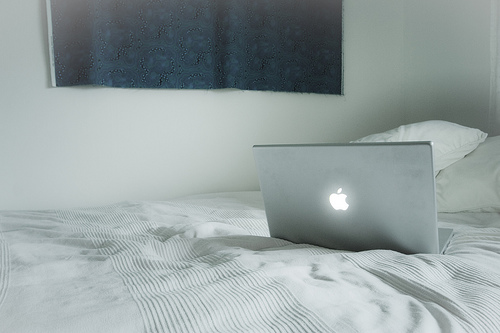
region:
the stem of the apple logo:
[333, 186, 343, 196]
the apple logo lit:
[329, 186, 349, 213]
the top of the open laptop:
[252, 137, 443, 255]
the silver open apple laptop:
[254, 135, 454, 259]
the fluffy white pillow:
[350, 118, 487, 179]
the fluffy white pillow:
[429, 132, 499, 207]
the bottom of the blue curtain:
[45, 2, 348, 96]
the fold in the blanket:
[360, 263, 458, 319]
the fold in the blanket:
[402, 293, 420, 331]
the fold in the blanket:
[426, 299, 452, 331]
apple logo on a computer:
[320, 183, 355, 217]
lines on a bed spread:
[155, 262, 227, 307]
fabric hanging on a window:
[120, 25, 263, 89]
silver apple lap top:
[238, 112, 463, 267]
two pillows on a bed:
[418, 91, 485, 210]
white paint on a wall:
[7, 103, 92, 160]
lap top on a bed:
[223, 116, 468, 291]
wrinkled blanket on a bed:
[56, 206, 174, 266]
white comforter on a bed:
[21, 220, 128, 322]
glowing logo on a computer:
[316, 181, 365, 216]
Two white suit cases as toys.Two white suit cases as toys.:
[132, 264, 133, 325]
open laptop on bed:
[240, 125, 461, 261]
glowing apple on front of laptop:
[315, 176, 366, 223]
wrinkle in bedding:
[36, 218, 117, 269]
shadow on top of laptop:
[355, 218, 416, 253]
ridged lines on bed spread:
[59, 199, 339, 331]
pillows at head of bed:
[342, 115, 497, 216]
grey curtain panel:
[37, 0, 368, 107]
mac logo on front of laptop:
[315, 178, 362, 222]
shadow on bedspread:
[355, 256, 472, 328]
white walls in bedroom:
[2, 0, 496, 217]